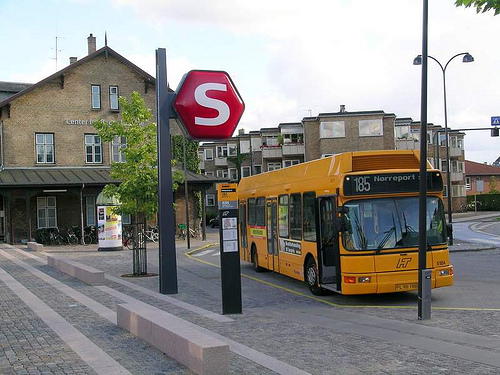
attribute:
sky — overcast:
[1, 1, 498, 168]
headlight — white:
[355, 273, 372, 284]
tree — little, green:
[113, 125, 161, 276]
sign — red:
[173, 68, 251, 137]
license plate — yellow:
[387, 279, 429, 301]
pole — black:
[159, 45, 174, 297]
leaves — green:
[453, 0, 486, 13]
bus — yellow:
[237, 150, 453, 296]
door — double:
[238, 200, 248, 260]